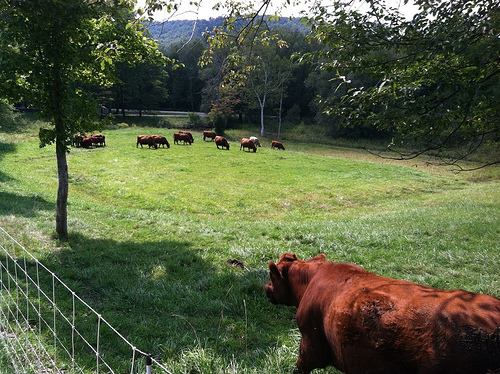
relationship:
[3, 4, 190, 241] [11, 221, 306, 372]
tree casting shadow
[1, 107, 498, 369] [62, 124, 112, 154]
grass next to animals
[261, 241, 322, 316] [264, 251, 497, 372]
head of animal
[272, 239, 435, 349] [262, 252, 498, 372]
brown fur on cow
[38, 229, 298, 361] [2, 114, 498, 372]
shadow on ground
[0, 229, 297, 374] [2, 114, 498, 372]
shadow on ground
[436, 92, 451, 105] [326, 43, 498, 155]
leaves on tree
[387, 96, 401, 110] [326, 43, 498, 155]
leaves on tree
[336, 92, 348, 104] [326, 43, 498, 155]
leaves on tree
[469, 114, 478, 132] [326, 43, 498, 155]
leaves on tree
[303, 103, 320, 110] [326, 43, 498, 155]
leaves on tree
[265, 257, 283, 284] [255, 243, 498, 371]
ear of cow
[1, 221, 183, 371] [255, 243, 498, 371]
fence next to cow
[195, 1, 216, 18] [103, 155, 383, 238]
sky above ground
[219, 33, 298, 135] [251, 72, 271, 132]
tree with trunk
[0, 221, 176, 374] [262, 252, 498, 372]
fence next to cow